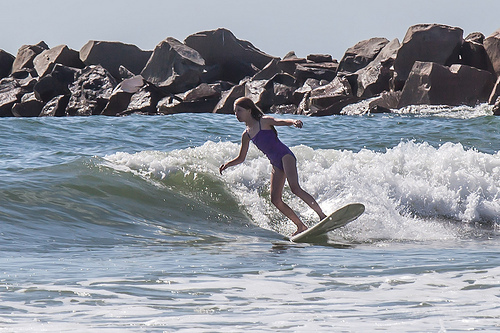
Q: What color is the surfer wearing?
A: Purple.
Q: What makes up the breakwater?
A: Great boulders.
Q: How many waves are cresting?
A: One.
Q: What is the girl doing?
A: Surfing.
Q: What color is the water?
A: Green.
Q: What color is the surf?
A: White.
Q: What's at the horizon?
A: Jetty.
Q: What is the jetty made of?
A: Great boulders.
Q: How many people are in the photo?
A: 1.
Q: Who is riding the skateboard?
A: The girl.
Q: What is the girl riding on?
A: Surfboard.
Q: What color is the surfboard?
A: White.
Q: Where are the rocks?
A: In the background, behind the surfer.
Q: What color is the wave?
A: White.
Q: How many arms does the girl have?
A: 2.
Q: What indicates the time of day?
A: Sunlight.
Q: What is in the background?
A: Rocks.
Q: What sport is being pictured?
A: Surfing.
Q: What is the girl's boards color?
A: White.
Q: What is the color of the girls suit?
A: Purple.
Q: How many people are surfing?
A: 1.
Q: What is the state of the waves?
A: Calm.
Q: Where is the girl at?
A: Ocean.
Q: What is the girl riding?
A: Surfboard.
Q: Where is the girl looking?
A: Sideways.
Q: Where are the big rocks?
A: On the beach.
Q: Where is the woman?
A: On a surfboard.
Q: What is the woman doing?
A: Surfing.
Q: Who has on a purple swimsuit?
A: The woman.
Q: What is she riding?
A: A surfboard.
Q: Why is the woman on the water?
A: To surf.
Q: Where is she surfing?
A: In the ocean.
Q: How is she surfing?
A: On a surfboard.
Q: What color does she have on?
A: Purple.